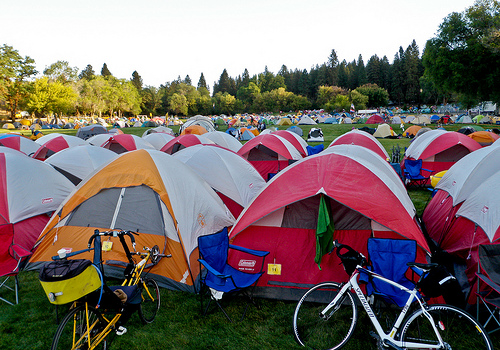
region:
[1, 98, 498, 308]
A field of tents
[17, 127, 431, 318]
Red and orange tents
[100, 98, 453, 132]
Tents in the distance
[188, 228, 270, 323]
A blue folding chair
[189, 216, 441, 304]
Two blue folding chairs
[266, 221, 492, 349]
A white bicycle on a blue chair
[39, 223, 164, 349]
A yellow reclining bicycle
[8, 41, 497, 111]
Trees beyond the tents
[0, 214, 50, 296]
A red folding chair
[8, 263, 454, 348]
Grass on the ground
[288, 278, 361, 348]
the wheel of a bicycle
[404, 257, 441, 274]
the seat of a bicycle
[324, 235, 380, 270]
a pair of black handlebars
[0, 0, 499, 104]
a gray sky overhead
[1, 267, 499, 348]
a patch of green grass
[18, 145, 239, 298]
an orange and white tent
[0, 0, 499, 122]
a row of green trees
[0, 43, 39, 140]
a tall green tree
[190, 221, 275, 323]
a blue and black chair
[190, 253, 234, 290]
the arm of a chair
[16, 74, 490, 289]
several tents in a field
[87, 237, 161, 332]
a yellow bike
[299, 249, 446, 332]
a parked white bike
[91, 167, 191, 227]
a orange and white tent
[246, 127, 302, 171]
two red and white tetsn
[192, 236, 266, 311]
a blue folding chair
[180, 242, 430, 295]
two blue folding chairs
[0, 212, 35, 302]
a red folding chair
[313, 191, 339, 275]
a green towel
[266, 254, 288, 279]
a yellow tag on a tent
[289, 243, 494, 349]
a light colored bicycle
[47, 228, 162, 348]
a yellow and black bicycle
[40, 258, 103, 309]
a yellow and black storage container attached to bicycle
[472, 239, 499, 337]
a dark grey and red folding chair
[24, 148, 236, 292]
an orange and grey tent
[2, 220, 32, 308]
a red folding chair with black trim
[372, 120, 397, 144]
a light colored peak-style tent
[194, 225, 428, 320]
two blue folding chairs with black trim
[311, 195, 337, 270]
a green shirt hanging from tent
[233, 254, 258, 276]
a white decal printed on red and grey tent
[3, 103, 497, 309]
a bunch of tents.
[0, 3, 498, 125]
Trees in a park.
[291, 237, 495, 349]
A bike on the grass.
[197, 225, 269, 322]
A blue chair on the grass.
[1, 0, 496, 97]
A hazy blue sky.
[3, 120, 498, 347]
Grass in the park.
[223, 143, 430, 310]
A red and white tent.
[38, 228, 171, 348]
A yellow bike on the grass.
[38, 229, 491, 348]
Two bikes on the grass.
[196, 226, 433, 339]
Two chairs on the grass.